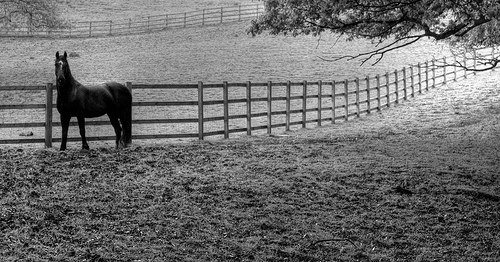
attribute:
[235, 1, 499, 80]
limbs — leafy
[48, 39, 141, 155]
horse — alert, standing, muscular, dark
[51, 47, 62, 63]
ear — pointed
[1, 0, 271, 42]
fence — wooden, long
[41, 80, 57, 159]
post — wooden, straight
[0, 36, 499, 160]
fence — long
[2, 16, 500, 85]
field — empty, grass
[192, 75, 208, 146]
post — straight, wood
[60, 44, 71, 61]
ear — pointed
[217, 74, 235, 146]
post — straight, wood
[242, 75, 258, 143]
post — straight, wood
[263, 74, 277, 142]
post — straight, wood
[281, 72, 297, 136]
post — wood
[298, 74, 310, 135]
post — wood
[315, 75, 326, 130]
post — wood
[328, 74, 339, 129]
post — wood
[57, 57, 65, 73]
spot — white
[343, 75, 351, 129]
post — wood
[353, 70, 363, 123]
post — straight, wood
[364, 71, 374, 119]
post — wood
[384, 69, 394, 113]
post — wood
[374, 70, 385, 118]
post — wood